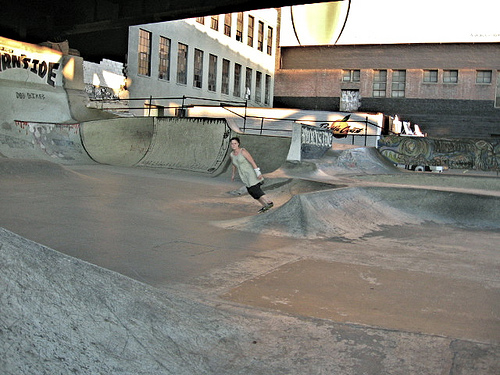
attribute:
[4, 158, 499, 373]
ground — grey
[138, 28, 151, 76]
window — broken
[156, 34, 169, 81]
window — broken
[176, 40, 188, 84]
window — broken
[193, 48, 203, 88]
window — broken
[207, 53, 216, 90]
window — broken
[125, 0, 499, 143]
building — commercial, industrial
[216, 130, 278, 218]
skateboarder — solitary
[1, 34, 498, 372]
skate park — all to herself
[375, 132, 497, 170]
graffiti — painted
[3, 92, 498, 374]
park — skateboard, features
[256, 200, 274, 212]
skateboard — park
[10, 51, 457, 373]
skate park — bleak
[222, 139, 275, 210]
woman — at skate park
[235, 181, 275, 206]
pants — black, woman's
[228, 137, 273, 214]
woman — skateboarding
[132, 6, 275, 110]
building — sun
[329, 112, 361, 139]
fruit — orange, green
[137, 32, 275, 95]
windows — missing small panes, of glass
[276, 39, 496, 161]
brick — red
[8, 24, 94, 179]
wall — park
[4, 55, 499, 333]
skatepark — burnside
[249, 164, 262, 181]
wristband — white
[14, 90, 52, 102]
sign — about bikes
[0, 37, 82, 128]
wall — skate park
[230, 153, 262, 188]
top — green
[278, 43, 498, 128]
building — brown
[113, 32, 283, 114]
building — brown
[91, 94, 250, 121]
railing — metal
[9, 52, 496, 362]
park — urban, skate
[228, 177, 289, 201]
pants — black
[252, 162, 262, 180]
wrist — bandaged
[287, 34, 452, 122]
building — brick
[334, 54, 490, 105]
windows — glass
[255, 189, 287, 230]
skating — track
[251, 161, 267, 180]
band — wrist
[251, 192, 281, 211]
skating — track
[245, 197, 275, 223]
skating — track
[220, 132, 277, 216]
skateboarder — solitary, female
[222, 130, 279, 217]
girl — on skateboard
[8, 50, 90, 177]
wall — at skate park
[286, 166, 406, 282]
ramps — cement, paved, for skateboarding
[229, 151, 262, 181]
top — long, gray